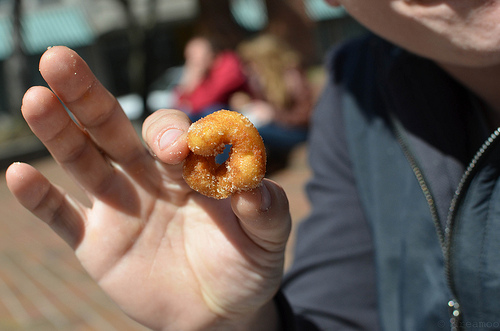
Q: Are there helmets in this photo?
A: No, there are no helmets.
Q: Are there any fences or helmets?
A: No, there are no helmets or fences.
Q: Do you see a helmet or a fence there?
A: No, there are no helmets or fences.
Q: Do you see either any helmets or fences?
A: No, there are no helmets or fences.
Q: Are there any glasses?
A: No, there are no glasses.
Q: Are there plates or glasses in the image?
A: No, there are no glasses or plates.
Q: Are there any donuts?
A: Yes, there is a donut.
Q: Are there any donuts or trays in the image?
A: Yes, there is a donut.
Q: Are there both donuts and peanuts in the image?
A: No, there is a donut but no peanuts.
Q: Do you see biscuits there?
A: No, there are no biscuits.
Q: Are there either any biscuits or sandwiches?
A: No, there are no biscuits or sandwiches.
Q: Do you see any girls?
A: No, there are no girls.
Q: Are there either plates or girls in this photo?
A: No, there are no girls or plates.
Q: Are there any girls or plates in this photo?
A: No, there are no girls or plates.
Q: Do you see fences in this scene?
A: No, there are no fences.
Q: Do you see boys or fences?
A: No, there are no fences or boys.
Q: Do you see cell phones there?
A: No, there are no cell phones.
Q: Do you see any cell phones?
A: No, there are no cell phones.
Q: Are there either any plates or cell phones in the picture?
A: No, there are no cell phones or plates.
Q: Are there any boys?
A: No, there are no boys.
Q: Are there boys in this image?
A: No, there are no boys.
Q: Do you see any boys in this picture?
A: No, there are no boys.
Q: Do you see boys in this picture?
A: No, there are no boys.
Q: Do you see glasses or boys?
A: No, there are no boys or glasses.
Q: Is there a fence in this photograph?
A: No, there are no fences.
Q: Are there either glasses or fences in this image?
A: No, there are no fences or glasses.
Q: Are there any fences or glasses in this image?
A: No, there are no fences or glasses.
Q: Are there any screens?
A: No, there are no screens.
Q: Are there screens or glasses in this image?
A: No, there are no screens or glasses.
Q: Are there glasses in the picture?
A: No, there are no glasses.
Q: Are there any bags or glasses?
A: No, there are no glasses or bags.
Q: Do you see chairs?
A: No, there are no chairs.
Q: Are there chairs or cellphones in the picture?
A: No, there are no chairs or cellphones.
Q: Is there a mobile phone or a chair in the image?
A: No, there are no chairs or cell phones.